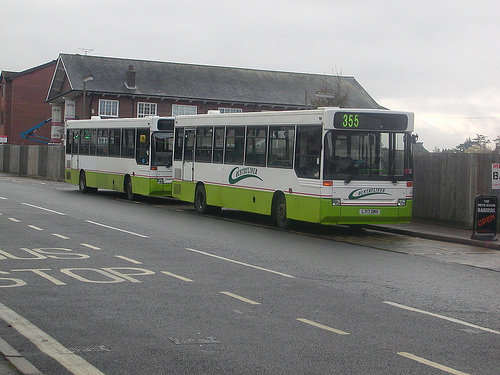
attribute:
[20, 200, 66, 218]
line — white, dotted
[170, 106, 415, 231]
bus — green, white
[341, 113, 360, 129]
number — green, 355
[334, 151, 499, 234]
fence — wood, wooden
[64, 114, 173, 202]
bus — green, white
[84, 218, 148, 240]
line — white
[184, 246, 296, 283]
line — white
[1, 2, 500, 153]
sky — full of clouds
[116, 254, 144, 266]
line — white